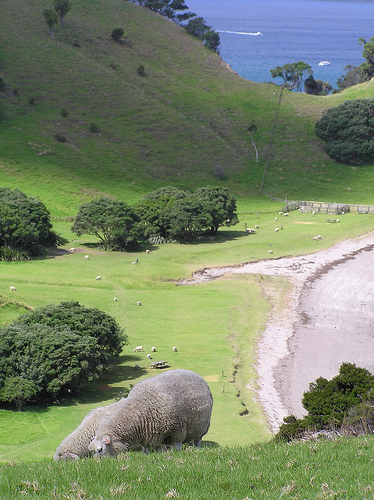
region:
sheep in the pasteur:
[88, 271, 102, 283]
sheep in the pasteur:
[8, 282, 20, 294]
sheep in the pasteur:
[130, 343, 143, 352]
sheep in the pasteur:
[171, 346, 181, 352]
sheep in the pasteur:
[146, 353, 153, 360]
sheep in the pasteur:
[151, 344, 157, 353]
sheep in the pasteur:
[49, 365, 213, 470]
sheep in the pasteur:
[243, 223, 259, 232]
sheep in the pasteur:
[335, 216, 344, 225]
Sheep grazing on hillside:
[41, 367, 213, 460]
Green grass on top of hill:
[3, 430, 371, 494]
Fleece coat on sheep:
[92, 371, 212, 449]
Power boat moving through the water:
[254, 30, 263, 36]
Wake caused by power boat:
[213, 29, 257, 37]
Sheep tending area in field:
[278, 197, 372, 217]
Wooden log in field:
[250, 136, 262, 164]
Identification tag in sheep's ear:
[103, 434, 112, 445]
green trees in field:
[1, 158, 239, 271]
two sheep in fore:
[59, 377, 204, 458]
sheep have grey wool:
[88, 369, 232, 464]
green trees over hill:
[296, 369, 363, 448]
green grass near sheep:
[181, 446, 355, 481]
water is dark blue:
[236, 20, 358, 81]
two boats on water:
[256, 11, 354, 80]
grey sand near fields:
[294, 256, 350, 377]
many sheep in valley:
[76, 209, 339, 356]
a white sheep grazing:
[171, 345, 177, 352]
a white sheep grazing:
[87, 370, 212, 457]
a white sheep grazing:
[145, 351, 150, 358]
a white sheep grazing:
[132, 345, 143, 350]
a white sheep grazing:
[136, 299, 140, 305]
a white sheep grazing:
[112, 295, 120, 303]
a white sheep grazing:
[95, 275, 101, 279]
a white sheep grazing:
[9, 285, 15, 291]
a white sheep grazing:
[83, 252, 89, 258]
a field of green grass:
[151, 87, 283, 215]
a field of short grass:
[147, 294, 244, 357]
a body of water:
[277, 15, 343, 70]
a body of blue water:
[251, 5, 350, 68]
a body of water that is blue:
[253, 13, 350, 78]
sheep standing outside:
[57, 351, 274, 498]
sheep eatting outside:
[37, 363, 179, 498]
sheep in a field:
[54, 376, 317, 497]